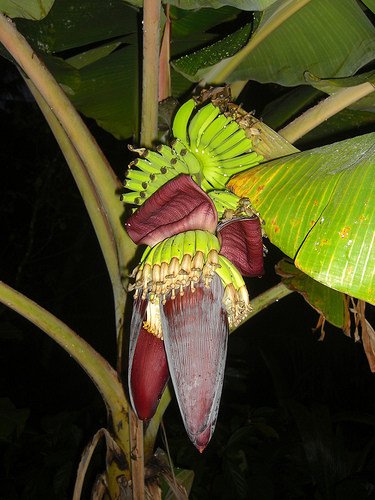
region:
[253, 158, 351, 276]
the leaves are green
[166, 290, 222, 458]
the bulb is purple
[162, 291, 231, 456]
the bulb is large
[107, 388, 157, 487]
the stalk is green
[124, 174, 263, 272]
the petal under fruit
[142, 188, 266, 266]
the petals are purple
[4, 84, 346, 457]
handles of bananas on a tree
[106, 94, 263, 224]
the bananas are green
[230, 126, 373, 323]
a big leaf of banana tree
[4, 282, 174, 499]
the trunk of banana tree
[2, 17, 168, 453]
green branches of banana tree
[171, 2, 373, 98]
leaf is color green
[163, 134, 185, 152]
a black tip on banana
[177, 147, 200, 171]
a black tip on banana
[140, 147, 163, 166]
a black tip on banana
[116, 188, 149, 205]
a black tip on banana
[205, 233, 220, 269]
A banana on a bunch.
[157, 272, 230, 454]
A large banana plant pod.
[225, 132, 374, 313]
A large green banana leaf.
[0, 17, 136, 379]
A large leaf on a banana bunch.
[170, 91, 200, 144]
A green banana in a bunch.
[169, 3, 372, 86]
A large green leaf on a tree.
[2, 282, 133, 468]
A large brown leaf.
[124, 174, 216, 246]
A large red banana plant pod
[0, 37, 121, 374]
The night sky above a tree.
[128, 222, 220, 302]
A bunch of bananas on a tree.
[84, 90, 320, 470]
a fruit tree at night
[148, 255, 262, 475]
red flowery covering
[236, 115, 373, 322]
big green leaves with spots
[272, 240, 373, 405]
green leaf with dead edges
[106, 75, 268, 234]
very green bananas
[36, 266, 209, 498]
stem of a fruit plant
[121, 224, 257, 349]
spot where bananas were cut off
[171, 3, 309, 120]
green leaves with white spots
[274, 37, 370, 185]
a light green stem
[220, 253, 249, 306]
a banana that hasn't matured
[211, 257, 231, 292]
a banana that hasn't matured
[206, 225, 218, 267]
a banana that hasn't matured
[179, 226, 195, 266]
a banana that hasn't matured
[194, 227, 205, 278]
a banana that hasn't matured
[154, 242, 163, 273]
a banana that hasn't matured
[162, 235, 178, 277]
a banana that hasn't matured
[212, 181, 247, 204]
a banana that hasn't matured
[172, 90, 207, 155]
a banana that hasn't matured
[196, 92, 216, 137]
a banana that hasn't matured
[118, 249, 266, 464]
this is a banana flower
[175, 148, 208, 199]
this is unripe banana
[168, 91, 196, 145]
this is unripe banana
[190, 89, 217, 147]
this is unripe banana